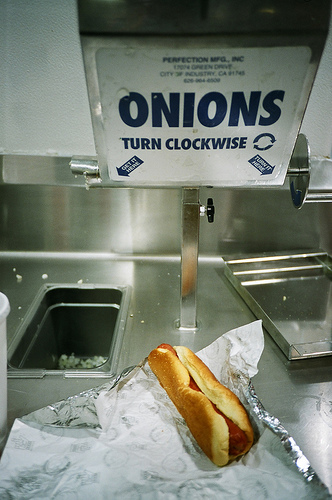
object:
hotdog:
[155, 335, 250, 467]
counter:
[5, 372, 332, 497]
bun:
[143, 344, 195, 374]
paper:
[29, 419, 170, 493]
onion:
[114, 86, 288, 124]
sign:
[101, 51, 289, 180]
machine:
[65, 0, 327, 216]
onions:
[118, 86, 283, 126]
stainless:
[11, 212, 168, 280]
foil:
[268, 414, 321, 483]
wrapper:
[16, 409, 170, 492]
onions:
[57, 340, 109, 369]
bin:
[24, 285, 106, 366]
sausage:
[230, 427, 249, 457]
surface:
[9, 193, 162, 234]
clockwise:
[165, 132, 248, 153]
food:
[54, 344, 102, 369]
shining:
[66, 228, 155, 288]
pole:
[173, 185, 206, 328]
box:
[93, 16, 291, 174]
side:
[0, 284, 12, 328]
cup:
[0, 290, 12, 449]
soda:
[0, 279, 14, 462]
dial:
[195, 193, 219, 229]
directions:
[113, 130, 276, 153]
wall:
[6, 2, 81, 161]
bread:
[150, 341, 252, 457]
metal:
[75, 224, 175, 281]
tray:
[262, 247, 332, 369]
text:
[106, 90, 242, 156]